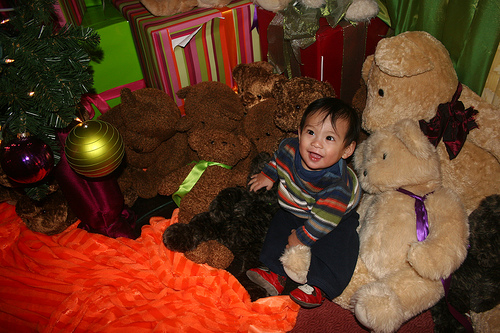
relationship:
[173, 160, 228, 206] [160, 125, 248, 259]
ribbon on teddy bear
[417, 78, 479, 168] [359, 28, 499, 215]
bow on teddy bear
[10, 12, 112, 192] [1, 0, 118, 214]
decorations on tree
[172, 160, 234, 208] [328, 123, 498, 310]
ribbon on bear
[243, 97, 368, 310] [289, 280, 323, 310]
baby wearing shoe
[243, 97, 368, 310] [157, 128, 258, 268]
baby on bear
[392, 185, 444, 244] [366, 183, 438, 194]
ribbon on neck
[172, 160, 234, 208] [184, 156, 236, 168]
ribbon around neck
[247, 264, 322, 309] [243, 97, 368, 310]
red shoes of baby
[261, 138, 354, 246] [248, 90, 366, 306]
sweater on baby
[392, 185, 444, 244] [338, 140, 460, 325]
ribbon around bear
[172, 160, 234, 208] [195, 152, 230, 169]
ribbon around neck